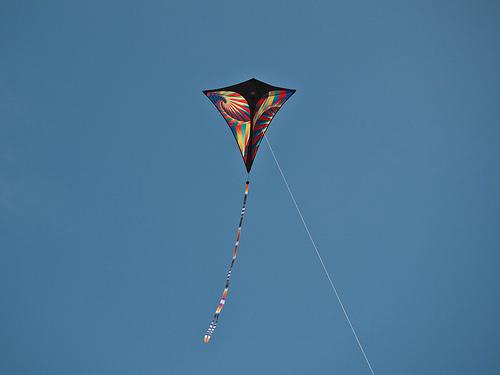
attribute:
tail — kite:
[205, 172, 253, 344]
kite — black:
[198, 75, 298, 200]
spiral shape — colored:
[220, 88, 253, 120]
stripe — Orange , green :
[234, 122, 246, 154]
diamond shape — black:
[201, 77, 296, 173]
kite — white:
[195, 72, 313, 193]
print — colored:
[219, 93, 248, 123]